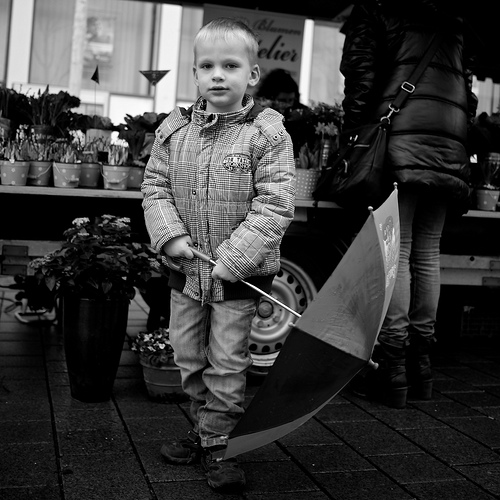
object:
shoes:
[201, 427, 251, 491]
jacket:
[137, 102, 291, 302]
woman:
[324, 1, 478, 397]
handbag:
[317, 114, 395, 204]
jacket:
[339, 1, 481, 213]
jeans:
[170, 290, 258, 440]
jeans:
[379, 187, 453, 346]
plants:
[122, 147, 130, 167]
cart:
[4, 182, 141, 263]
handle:
[165, 242, 305, 319]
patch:
[222, 149, 256, 178]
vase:
[53, 282, 134, 403]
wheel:
[212, 224, 358, 393]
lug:
[257, 298, 277, 323]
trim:
[166, 267, 275, 303]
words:
[289, 43, 303, 68]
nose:
[209, 70, 228, 84]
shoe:
[158, 424, 205, 470]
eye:
[219, 59, 244, 75]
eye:
[194, 59, 216, 75]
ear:
[246, 62, 264, 91]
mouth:
[202, 83, 234, 97]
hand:
[157, 232, 199, 262]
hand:
[209, 259, 243, 290]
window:
[23, 1, 163, 104]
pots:
[57, 178, 69, 190]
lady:
[259, 68, 312, 113]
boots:
[356, 345, 413, 412]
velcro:
[205, 445, 226, 462]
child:
[138, 13, 304, 495]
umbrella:
[176, 173, 408, 465]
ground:
[2, 308, 499, 499]